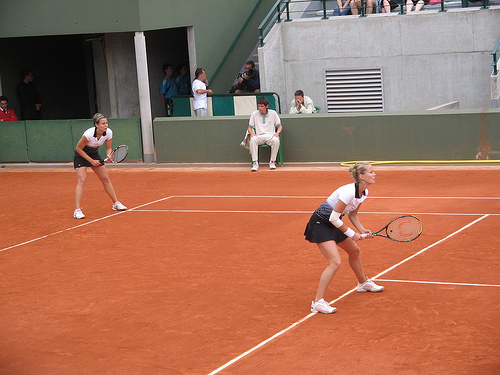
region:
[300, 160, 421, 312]
blonde woman holding tennis racquet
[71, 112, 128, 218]
brunette woman holding tennis racquet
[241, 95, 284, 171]
man wearing white is sitting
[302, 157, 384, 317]
blonde woman is wearing black skirt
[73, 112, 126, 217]
brunette woman is wearing black skirt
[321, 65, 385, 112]
white vent is in gray wall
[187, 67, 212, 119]
man wearing white shirt is behind wall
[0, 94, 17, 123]
person wearing red coat is behind green wall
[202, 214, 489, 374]
white lines are on red court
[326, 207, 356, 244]
white bands on woman's arm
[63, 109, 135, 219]
a woman holding a tennis rack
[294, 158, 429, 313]
a woman holding a tennis rack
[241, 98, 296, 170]
a man sitting in a chair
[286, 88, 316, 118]
a man with his hands cup to his mouth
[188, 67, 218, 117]
a man on his cell phone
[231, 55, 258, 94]
a man holding a camera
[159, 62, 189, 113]
two security officers at a tennis match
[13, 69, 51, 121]
a man standing along a wall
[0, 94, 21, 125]
a man wearing a red jacket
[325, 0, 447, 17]
people sitting in the audience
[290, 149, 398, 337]
This is a person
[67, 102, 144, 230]
This is a person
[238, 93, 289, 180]
This is a person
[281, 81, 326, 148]
This is a person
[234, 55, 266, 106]
This is a person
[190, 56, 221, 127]
This is a person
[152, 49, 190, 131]
This is a person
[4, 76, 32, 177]
This is a person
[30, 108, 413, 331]
two women playing tennis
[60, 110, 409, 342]
two women playing doubles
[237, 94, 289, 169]
the linesman at a tennis match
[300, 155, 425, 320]
a woman playing tennis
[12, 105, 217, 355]
a woman playing tennis on a clay court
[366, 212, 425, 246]
a black and white tennis racket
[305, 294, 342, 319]
a white tennis shoe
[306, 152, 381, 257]
a woman wearing a tennis outfit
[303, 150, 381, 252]
a woman wearing a tennis skirt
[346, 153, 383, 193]
a woman with blonde hair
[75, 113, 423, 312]
two women playing tennis on a tennis scourt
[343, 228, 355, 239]
woman with a white wristband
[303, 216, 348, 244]
woman wearing a dark blue skirt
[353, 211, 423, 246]
woman holding a tennis racket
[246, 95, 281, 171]
a man sitting in a green chair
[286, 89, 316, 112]
a man with his hand on his face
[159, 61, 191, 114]
two men with their back against a wall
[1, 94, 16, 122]
a man wearing a red shirt in the dugout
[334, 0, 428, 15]
legs of people watching a tennis match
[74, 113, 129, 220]
woman ready to hit a ball